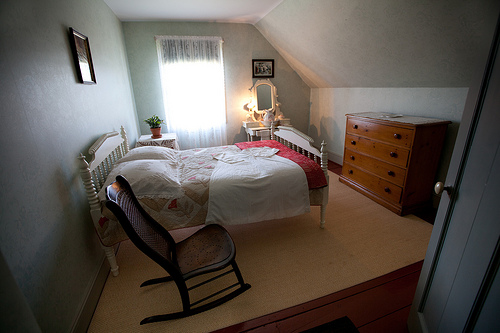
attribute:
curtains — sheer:
[156, 38, 229, 152]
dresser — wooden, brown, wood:
[342, 114, 451, 225]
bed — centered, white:
[82, 121, 328, 226]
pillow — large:
[116, 163, 182, 199]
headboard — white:
[80, 124, 130, 234]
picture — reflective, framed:
[66, 25, 97, 85]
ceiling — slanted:
[107, 3, 479, 90]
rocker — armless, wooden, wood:
[104, 174, 252, 327]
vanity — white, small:
[242, 81, 292, 140]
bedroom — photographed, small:
[1, 2, 499, 332]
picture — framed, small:
[251, 58, 277, 81]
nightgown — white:
[207, 145, 310, 230]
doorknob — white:
[429, 181, 451, 198]